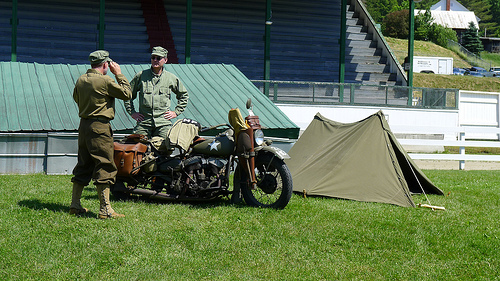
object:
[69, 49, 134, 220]
soldier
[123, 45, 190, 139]
soldier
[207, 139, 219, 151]
star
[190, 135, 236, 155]
tank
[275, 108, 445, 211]
tent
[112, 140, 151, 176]
bag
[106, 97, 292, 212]
motorcycle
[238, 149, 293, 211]
wheel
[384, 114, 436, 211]
rope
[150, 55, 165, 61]
sunglasses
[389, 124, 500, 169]
fence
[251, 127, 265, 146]
headlight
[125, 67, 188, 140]
uniform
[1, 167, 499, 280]
grass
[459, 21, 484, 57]
tree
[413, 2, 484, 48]
house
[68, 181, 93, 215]
boot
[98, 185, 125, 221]
boot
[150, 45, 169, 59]
hat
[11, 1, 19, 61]
post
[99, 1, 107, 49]
post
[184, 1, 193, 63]
post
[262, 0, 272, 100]
post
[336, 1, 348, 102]
post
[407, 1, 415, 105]
post